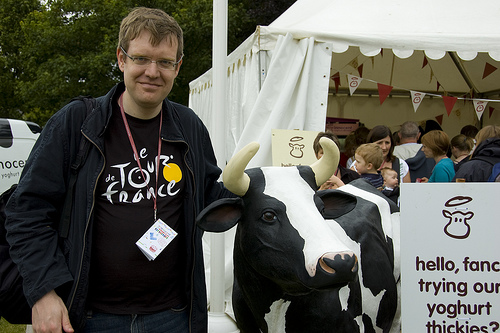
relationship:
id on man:
[135, 214, 180, 264] [5, 9, 248, 329]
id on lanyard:
[135, 214, 180, 264] [115, 85, 170, 225]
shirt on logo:
[71, 99, 199, 309] [101, 148, 182, 204]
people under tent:
[312, 119, 500, 205] [186, 0, 486, 203]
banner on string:
[347, 74, 489, 121] [348, 68, 498, 105]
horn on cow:
[313, 137, 343, 193] [223, 131, 400, 331]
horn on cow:
[215, 140, 265, 197] [223, 131, 400, 331]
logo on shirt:
[102, 148, 178, 201] [83, 94, 190, 312]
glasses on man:
[122, 47, 186, 77] [5, 9, 248, 329]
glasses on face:
[122, 47, 186, 77] [115, 31, 180, 103]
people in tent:
[352, 112, 490, 194] [187, 1, 499, 168]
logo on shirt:
[101, 148, 182, 204] [78, 105, 205, 321]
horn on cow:
[223, 141, 260, 196] [191, 135, 409, 331]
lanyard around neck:
[112, 85, 173, 266] [113, 78, 181, 114]